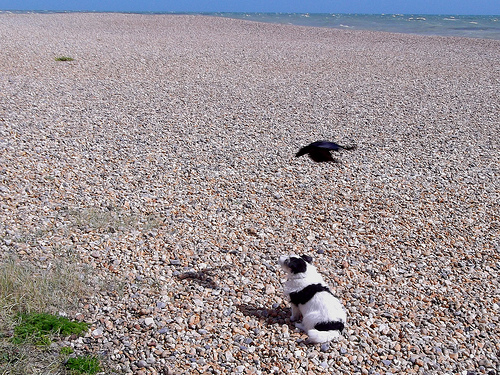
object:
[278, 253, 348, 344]
dog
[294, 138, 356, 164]
bird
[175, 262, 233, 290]
shadow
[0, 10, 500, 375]
beach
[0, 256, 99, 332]
weeds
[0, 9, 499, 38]
ocean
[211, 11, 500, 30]
waves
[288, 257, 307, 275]
ear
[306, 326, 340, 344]
tail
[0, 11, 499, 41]
shoreline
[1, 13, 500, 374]
gravel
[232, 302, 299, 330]
shadow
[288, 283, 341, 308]
stripe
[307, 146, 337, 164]
wing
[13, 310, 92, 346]
grass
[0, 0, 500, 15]
sky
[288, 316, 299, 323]
paw